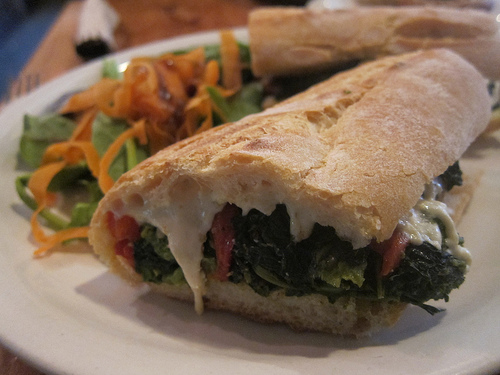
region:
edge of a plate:
[43, 348, 62, 365]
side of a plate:
[393, 351, 428, 373]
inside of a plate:
[178, 310, 203, 334]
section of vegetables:
[96, 159, 124, 169]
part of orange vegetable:
[190, 77, 211, 93]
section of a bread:
[352, 119, 393, 171]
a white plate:
[443, 293, 476, 352]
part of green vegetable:
[388, 254, 428, 284]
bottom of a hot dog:
[305, 297, 335, 327]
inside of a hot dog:
[423, 136, 454, 201]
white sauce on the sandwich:
[114, 182, 226, 316]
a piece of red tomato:
[203, 207, 248, 282]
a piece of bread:
[88, 45, 487, 238]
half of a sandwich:
[84, 42, 498, 333]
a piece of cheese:
[91, 107, 150, 196]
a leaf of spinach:
[11, 104, 96, 172]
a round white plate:
[0, 22, 497, 372]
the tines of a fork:
[7, 65, 53, 102]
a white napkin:
[67, 0, 124, 53]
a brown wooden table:
[0, 0, 267, 121]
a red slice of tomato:
[199, 201, 241, 290]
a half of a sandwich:
[77, 46, 493, 351]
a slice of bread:
[79, 41, 495, 250]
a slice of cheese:
[87, 120, 142, 195]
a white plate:
[0, 20, 497, 373]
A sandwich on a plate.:
[35, 38, 481, 356]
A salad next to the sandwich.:
[41, 41, 466, 312]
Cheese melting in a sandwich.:
[145, 160, 271, 325]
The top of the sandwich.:
[115, 120, 440, 230]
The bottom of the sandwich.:
[136, 246, 427, 327]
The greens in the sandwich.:
[262, 230, 462, 295]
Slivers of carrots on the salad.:
[25, 65, 156, 180]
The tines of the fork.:
[5, 60, 45, 95]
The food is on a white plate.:
[35, 41, 495, 361]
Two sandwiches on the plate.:
[70, 1, 496, 366]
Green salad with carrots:
[51, 58, 285, 164]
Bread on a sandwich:
[211, 46, 426, 221]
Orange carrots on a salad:
[68, 51, 219, 145]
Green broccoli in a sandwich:
[136, 181, 454, 285]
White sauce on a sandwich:
[116, 196, 257, 309]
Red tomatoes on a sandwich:
[173, 171, 453, 310]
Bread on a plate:
[236, 6, 474, 117]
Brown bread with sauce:
[220, 40, 442, 212]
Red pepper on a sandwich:
[365, 216, 423, 274]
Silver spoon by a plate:
[61, 7, 142, 60]